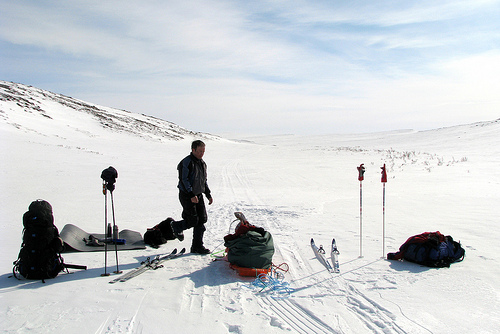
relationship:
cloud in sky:
[1, 0, 500, 139] [24, 15, 481, 153]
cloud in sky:
[1, 0, 500, 139] [0, 3, 499, 142]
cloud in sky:
[1, 0, 500, 139] [299, 13, 493, 56]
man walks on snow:
[169, 127, 216, 256] [176, 251, 216, 292]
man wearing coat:
[149, 137, 216, 255] [163, 155, 222, 200]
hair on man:
[191, 137, 203, 155] [144, 139, 218, 258]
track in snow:
[266, 303, 391, 327] [420, 178, 486, 218]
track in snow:
[223, 190, 416, 334] [90, 272, 417, 332]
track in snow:
[223, 190, 416, 334] [0, 69, 497, 330]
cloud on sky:
[1, 0, 500, 139] [0, 3, 499, 142]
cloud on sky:
[1, 1, 171, 79] [0, 3, 499, 142]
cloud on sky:
[1, 0, 500, 139] [311, 37, 418, 74]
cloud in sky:
[1, 0, 500, 139] [351, 23, 480, 95]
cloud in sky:
[1, 1, 171, 79] [351, 23, 480, 95]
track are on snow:
[223, 190, 416, 334] [0, 69, 497, 330]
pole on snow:
[375, 161, 392, 256] [285, 299, 363, 331]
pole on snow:
[358, 160, 368, 260] [285, 299, 363, 331]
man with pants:
[149, 137, 216, 255] [146, 195, 208, 255]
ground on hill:
[0, 76, 197, 148] [7, 84, 41, 118]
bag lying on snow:
[387, 229, 469, 270] [410, 180, 481, 220]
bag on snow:
[387, 229, 469, 270] [0, 69, 497, 330]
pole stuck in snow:
[358, 160, 368, 260] [0, 69, 497, 330]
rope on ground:
[249, 270, 299, 297] [197, 274, 400, 328]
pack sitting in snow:
[12, 187, 74, 284] [55, 293, 248, 330]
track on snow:
[223, 190, 416, 334] [147, 314, 175, 332]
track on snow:
[223, 190, 416, 334] [139, 308, 185, 329]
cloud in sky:
[1, 0, 500, 139] [277, 19, 374, 30]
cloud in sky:
[1, 0, 500, 139] [56, 6, 474, 143]